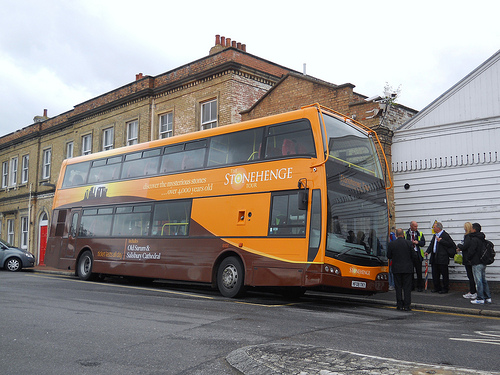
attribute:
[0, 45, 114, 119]
clouds — white 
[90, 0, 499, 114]
clouds — white 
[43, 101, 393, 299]
orange bus — orange 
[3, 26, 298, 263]
brick building — large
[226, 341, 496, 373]
island — concrete 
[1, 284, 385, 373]
road — grey 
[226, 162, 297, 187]
letters — White 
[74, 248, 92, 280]
tire — back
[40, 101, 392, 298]
bus — tall, yellow, maroon, double decker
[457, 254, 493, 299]
jeans — blue 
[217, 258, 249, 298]
wheel — Rear 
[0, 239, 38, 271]
car — silver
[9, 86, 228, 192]
windows — white  , long row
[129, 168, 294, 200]
letters — white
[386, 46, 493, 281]
building — large , white  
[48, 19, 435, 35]
sky — bright, cloudy 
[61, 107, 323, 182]
part — top 